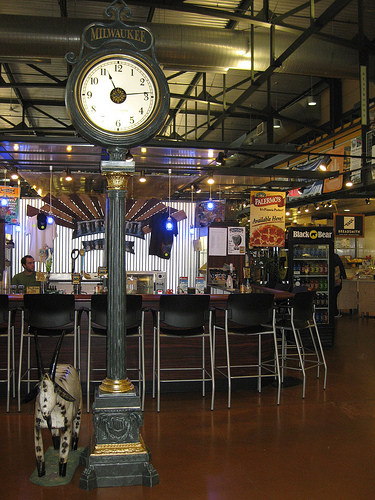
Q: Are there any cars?
A: No, there are no cars.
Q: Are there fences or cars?
A: No, there are no cars or fences.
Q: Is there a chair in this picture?
A: Yes, there is a chair.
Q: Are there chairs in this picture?
A: Yes, there is a chair.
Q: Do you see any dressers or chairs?
A: Yes, there is a chair.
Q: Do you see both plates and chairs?
A: No, there is a chair but no plates.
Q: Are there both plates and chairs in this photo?
A: No, there is a chair but no plates.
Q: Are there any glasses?
A: No, there are no glasses.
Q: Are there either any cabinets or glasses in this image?
A: No, there are no glasses or cabinets.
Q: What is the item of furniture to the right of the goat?
A: The piece of furniture is a chair.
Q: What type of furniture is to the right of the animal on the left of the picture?
A: The piece of furniture is a chair.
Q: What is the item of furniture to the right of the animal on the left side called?
A: The piece of furniture is a chair.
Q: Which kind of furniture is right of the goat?
A: The piece of furniture is a chair.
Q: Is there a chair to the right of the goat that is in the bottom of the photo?
A: Yes, there is a chair to the right of the goat.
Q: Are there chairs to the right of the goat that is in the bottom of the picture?
A: Yes, there is a chair to the right of the goat.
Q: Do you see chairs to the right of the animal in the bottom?
A: Yes, there is a chair to the right of the goat.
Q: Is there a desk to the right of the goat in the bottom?
A: No, there is a chair to the right of the goat.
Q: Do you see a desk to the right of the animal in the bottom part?
A: No, there is a chair to the right of the goat.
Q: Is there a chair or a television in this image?
A: Yes, there is a chair.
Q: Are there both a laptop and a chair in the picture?
A: No, there is a chair but no laptops.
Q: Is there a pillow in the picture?
A: No, there are no pillows.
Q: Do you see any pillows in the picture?
A: No, there are no pillows.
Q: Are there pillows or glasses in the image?
A: No, there are no pillows or glasses.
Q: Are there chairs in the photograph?
A: Yes, there is a chair.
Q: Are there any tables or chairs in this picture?
A: Yes, there is a chair.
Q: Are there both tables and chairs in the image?
A: No, there is a chair but no tables.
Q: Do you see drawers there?
A: No, there are no drawers.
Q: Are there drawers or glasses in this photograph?
A: No, there are no drawers or glasses.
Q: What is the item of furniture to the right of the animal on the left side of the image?
A: The piece of furniture is a chair.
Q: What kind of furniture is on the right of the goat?
A: The piece of furniture is a chair.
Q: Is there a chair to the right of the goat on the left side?
A: Yes, there is a chair to the right of the goat.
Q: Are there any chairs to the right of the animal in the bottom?
A: Yes, there is a chair to the right of the goat.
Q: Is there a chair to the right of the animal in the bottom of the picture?
A: Yes, there is a chair to the right of the goat.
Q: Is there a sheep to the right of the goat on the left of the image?
A: No, there is a chair to the right of the goat.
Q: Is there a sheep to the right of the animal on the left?
A: No, there is a chair to the right of the goat.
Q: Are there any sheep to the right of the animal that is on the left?
A: No, there is a chair to the right of the goat.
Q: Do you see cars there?
A: No, there are no cars.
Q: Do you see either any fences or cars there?
A: No, there are no cars or fences.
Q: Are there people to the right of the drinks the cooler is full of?
A: Yes, there is a person to the right of the drinks.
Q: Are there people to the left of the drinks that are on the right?
A: No, the person is to the right of the drinks.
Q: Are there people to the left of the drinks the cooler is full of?
A: No, the person is to the right of the drinks.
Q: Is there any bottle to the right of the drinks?
A: No, there is a person to the right of the drinks.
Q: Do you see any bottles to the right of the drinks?
A: No, there is a person to the right of the drinks.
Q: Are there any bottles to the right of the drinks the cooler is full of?
A: No, there is a person to the right of the drinks.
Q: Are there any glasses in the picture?
A: No, there are no glasses.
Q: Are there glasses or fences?
A: No, there are no glasses or fences.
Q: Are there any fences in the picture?
A: No, there are no fences.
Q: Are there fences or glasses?
A: No, there are no fences or glasses.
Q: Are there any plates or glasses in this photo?
A: No, there are no glasses or plates.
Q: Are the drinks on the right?
A: Yes, the drinks are on the right of the image.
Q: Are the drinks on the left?
A: No, the drinks are on the right of the image.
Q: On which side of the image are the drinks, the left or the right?
A: The drinks are on the right of the image.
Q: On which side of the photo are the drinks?
A: The drinks are on the right of the image.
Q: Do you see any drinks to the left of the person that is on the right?
A: Yes, there are drinks to the left of the person.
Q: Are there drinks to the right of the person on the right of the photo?
A: No, the drinks are to the left of the person.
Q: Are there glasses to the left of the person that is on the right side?
A: No, there are drinks to the left of the person.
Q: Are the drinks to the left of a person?
A: Yes, the drinks are to the left of a person.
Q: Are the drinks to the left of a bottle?
A: No, the drinks are to the left of a person.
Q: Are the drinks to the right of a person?
A: No, the drinks are to the left of a person.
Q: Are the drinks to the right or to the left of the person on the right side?
A: The drinks are to the left of the person.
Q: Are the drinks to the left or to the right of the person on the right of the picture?
A: The drinks are to the left of the person.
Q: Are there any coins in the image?
A: No, there are no coins.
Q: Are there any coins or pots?
A: No, there are no coins or pots.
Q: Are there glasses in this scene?
A: No, there are no glasses.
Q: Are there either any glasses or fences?
A: No, there are no glasses or fences.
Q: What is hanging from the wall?
A: The shirt is hanging from the wall.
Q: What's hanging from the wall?
A: The shirt is hanging from the wall.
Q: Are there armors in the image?
A: No, there are no armors.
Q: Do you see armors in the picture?
A: No, there are no armors.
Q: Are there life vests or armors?
A: No, there are no armors or life vests.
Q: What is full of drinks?
A: The cooler is full of drinks.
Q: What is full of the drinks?
A: The cooler is full of drinks.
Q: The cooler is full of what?
A: The cooler is full of drinks.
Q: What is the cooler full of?
A: The cooler is full of drinks.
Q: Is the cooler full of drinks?
A: Yes, the cooler is full of drinks.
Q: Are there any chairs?
A: Yes, there is a chair.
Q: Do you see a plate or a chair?
A: Yes, there is a chair.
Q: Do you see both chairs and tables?
A: No, there is a chair but no tables.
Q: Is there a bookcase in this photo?
A: No, there are no bookcases.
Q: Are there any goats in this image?
A: Yes, there is a goat.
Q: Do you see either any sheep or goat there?
A: Yes, there is a goat.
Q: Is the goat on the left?
A: Yes, the goat is on the left of the image.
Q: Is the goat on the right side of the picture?
A: No, the goat is on the left of the image.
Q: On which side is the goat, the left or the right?
A: The goat is on the left of the image.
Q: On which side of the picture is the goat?
A: The goat is on the left of the image.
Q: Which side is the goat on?
A: The goat is on the left of the image.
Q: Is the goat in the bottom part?
A: Yes, the goat is in the bottom of the image.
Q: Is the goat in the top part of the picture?
A: No, the goat is in the bottom of the image.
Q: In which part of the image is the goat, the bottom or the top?
A: The goat is in the bottom of the image.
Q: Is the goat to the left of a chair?
A: Yes, the goat is to the left of a chair.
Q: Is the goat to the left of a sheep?
A: No, the goat is to the left of a chair.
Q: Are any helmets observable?
A: No, there are no helmets.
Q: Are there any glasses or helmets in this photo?
A: No, there are no helmets or glasses.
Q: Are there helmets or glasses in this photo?
A: No, there are no helmets or glasses.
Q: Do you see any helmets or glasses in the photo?
A: No, there are no helmets or glasses.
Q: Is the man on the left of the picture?
A: Yes, the man is on the left of the image.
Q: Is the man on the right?
A: No, the man is on the left of the image.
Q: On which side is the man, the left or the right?
A: The man is on the left of the image.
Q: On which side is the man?
A: The man is on the left of the image.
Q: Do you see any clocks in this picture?
A: Yes, there is a clock.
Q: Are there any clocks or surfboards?
A: Yes, there is a clock.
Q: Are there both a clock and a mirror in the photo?
A: No, there is a clock but no mirrors.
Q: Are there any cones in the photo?
A: No, there are no cones.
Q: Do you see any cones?
A: No, there are no cones.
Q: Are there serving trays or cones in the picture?
A: No, there are no cones or serving trays.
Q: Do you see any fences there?
A: No, there are no fences.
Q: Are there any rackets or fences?
A: No, there are no fences or rackets.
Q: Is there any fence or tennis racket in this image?
A: No, there are no fences or rackets.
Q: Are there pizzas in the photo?
A: Yes, there is a pizza.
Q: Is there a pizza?
A: Yes, there is a pizza.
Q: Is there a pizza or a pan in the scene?
A: Yes, there is a pizza.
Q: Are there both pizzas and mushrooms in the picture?
A: No, there is a pizza but no mushrooms.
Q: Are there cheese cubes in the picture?
A: No, there are no cheese cubes.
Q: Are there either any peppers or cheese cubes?
A: No, there are no cheese cubes or peppers.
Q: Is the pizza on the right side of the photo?
A: Yes, the pizza is on the right of the image.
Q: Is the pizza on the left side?
A: No, the pizza is on the right of the image.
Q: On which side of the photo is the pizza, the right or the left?
A: The pizza is on the right of the image.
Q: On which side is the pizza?
A: The pizza is on the right of the image.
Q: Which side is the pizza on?
A: The pizza is on the right of the image.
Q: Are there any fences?
A: No, there are no fences.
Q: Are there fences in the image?
A: No, there are no fences.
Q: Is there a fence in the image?
A: No, there are no fences.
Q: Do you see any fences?
A: No, there are no fences.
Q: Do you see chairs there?
A: Yes, there is a chair.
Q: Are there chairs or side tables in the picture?
A: Yes, there is a chair.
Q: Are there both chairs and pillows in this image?
A: No, there is a chair but no pillows.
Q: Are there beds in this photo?
A: No, there are no beds.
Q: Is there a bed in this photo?
A: No, there are no beds.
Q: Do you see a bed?
A: No, there are no beds.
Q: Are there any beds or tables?
A: No, there are no beds or tables.